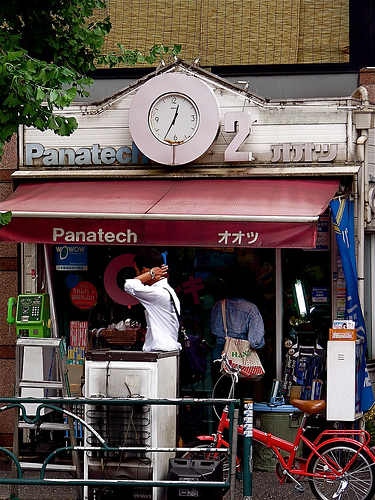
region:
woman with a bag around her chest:
[210, 291, 270, 374]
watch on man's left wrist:
[143, 261, 161, 285]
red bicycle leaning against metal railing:
[185, 388, 365, 486]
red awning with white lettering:
[4, 175, 345, 243]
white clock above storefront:
[116, 70, 227, 182]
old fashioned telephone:
[5, 288, 49, 350]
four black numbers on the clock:
[148, 89, 201, 154]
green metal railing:
[5, 389, 257, 489]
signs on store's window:
[55, 242, 102, 312]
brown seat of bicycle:
[280, 393, 334, 419]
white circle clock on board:
[117, 62, 255, 221]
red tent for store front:
[39, 165, 348, 288]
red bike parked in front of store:
[193, 388, 372, 491]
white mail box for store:
[320, 313, 357, 419]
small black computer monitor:
[183, 444, 229, 486]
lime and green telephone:
[8, 292, 56, 340]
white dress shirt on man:
[116, 264, 184, 348]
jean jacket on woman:
[217, 305, 286, 353]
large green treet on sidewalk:
[14, 3, 118, 135]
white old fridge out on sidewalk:
[92, 336, 160, 498]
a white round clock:
[126, 69, 221, 168]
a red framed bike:
[181, 355, 373, 495]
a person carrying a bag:
[210, 273, 274, 382]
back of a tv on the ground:
[167, 456, 229, 498]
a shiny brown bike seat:
[287, 394, 327, 414]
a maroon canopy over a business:
[2, 171, 337, 254]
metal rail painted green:
[3, 390, 259, 498]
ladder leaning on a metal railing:
[9, 332, 85, 497]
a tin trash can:
[252, 403, 303, 474]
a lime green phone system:
[5, 292, 48, 339]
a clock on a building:
[127, 73, 218, 165]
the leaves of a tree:
[2, 18, 62, 105]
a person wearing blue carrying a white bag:
[207, 278, 268, 401]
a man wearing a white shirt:
[124, 255, 189, 356]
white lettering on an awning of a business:
[45, 223, 149, 243]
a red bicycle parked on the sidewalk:
[178, 363, 374, 488]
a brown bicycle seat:
[283, 390, 330, 418]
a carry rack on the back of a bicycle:
[315, 423, 372, 443]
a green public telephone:
[5, 284, 54, 349]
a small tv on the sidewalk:
[164, 453, 229, 497]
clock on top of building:
[149, 90, 198, 146]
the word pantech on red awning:
[49, 222, 142, 248]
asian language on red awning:
[214, 222, 244, 249]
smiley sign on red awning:
[243, 227, 260, 246]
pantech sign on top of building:
[25, 134, 149, 168]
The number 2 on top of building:
[217, 103, 256, 165]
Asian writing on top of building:
[265, 137, 314, 168]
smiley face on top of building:
[313, 141, 339, 161]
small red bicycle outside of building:
[170, 350, 374, 498]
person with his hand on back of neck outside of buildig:
[118, 249, 182, 363]